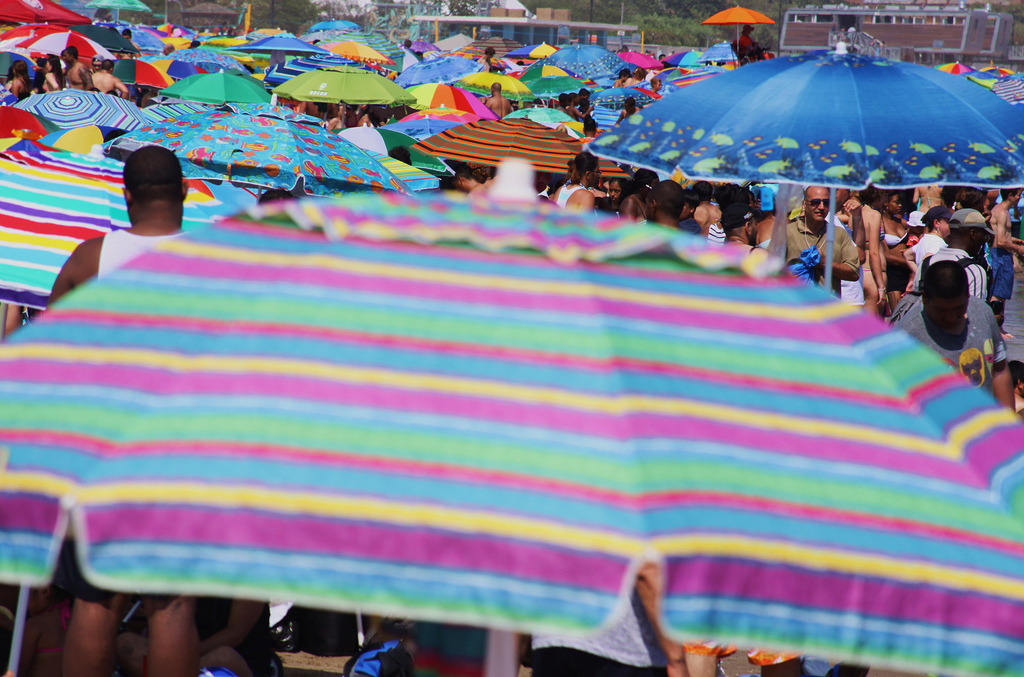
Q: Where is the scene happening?
A: In a crowded area.